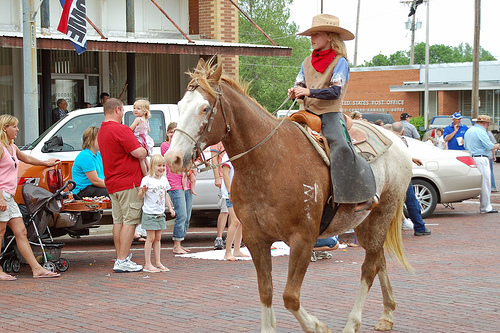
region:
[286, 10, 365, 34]
tan cowboy hat on head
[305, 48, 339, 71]
red bandanna around neck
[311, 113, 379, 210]
chaps on legs of kid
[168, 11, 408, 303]
young girl riding a horse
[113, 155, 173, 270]
young girl standing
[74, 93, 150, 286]
man holding a child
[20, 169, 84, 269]
black stroller on ground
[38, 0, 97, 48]
flag hanging down from pole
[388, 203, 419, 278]
blond hair of horse tail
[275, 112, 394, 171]
saddle on top of horse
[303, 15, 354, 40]
tan straw cowboy hat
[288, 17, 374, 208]
girl wearing cowboy outfit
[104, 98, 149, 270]
man holding little girl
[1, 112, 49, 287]
woman wearing tank top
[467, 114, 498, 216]
man wearing blue shirt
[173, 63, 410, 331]
brown and white shirt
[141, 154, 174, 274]
girl watching parade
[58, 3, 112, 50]
welcome flag on wood pole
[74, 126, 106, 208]
woman sitting in truck bed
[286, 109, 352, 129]
orange saddle on horse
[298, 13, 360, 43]
a brown hat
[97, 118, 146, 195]
a man's red shirt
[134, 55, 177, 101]
the window of a building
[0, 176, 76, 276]
a baby stroller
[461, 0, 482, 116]
a long wooden pole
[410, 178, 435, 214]
part of a car tire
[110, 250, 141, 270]
a man's white tennis shoe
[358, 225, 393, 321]
the leg of a horse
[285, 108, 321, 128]
a brown horse saddle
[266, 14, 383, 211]
Young girl wearing beige cowboy hat riding horse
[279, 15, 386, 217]
Young girl riding horse wearing red handkerchief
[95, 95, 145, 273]
Man wearing red shirt holding young child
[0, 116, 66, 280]
Woman next to stroller leaning on orange car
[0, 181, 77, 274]
Gray and black stroller next to orange car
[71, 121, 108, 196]
Person wearing blue top sitting on bed of truck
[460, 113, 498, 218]
Man in blue button down shirt near champagne colored car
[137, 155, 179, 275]
Young girl next to man in red shirt is wearing green skirt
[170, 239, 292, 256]
White blanket on ground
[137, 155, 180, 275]
Young girl in white shirt is blond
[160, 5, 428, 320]
young girl with cowgirl hat on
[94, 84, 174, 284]
man in red shirt holding little girl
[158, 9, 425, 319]
girl with red bandana and chaps riding horse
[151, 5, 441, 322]
girl in western clothing riding brown and white horse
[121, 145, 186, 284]
blonde girl in flip flops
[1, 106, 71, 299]
blonde woman leaning on orange truck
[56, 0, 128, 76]
red white and blue welcome flag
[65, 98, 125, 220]
woman in blue shirt sitting on back of orange truck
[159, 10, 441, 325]
girl riding brown and white horse